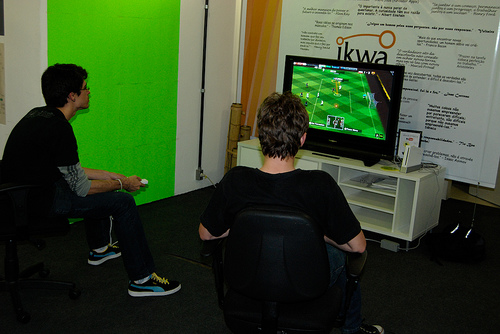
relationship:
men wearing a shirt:
[1, 62, 184, 297] [2, 104, 91, 218]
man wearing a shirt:
[197, 92, 384, 333] [198, 156, 361, 246]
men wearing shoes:
[1, 62, 184, 297] [85, 243, 182, 297]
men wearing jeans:
[1, 62, 184, 297] [53, 183, 156, 280]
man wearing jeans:
[197, 92, 384, 333] [328, 245, 365, 333]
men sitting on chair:
[1, 62, 184, 297] [1, 160, 83, 324]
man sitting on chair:
[197, 92, 384, 333] [199, 205, 368, 333]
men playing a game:
[1, 62, 184, 297] [398, 144, 422, 173]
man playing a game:
[197, 92, 384, 333] [398, 144, 422, 173]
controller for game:
[139, 177, 149, 186] [398, 144, 422, 173]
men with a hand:
[1, 62, 184, 297] [127, 176, 148, 192]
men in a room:
[1, 62, 367, 297] [0, 2, 498, 333]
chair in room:
[1, 160, 83, 324] [0, 2, 498, 333]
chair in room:
[199, 205, 368, 333] [0, 2, 498, 333]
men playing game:
[1, 62, 367, 297] [398, 144, 422, 173]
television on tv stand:
[282, 54, 405, 165] [235, 137, 446, 252]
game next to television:
[398, 144, 422, 173] [282, 54, 405, 165]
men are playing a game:
[1, 62, 367, 297] [398, 144, 422, 173]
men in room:
[1, 62, 367, 297] [0, 2, 498, 333]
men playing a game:
[1, 62, 367, 297] [398, 144, 422, 173]